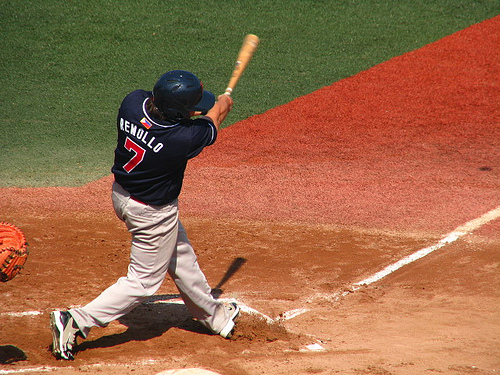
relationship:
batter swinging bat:
[51, 70, 239, 362] [223, 32, 259, 95]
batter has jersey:
[51, 70, 239, 362] [112, 90, 217, 207]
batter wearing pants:
[51, 70, 239, 362] [68, 180, 220, 337]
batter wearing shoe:
[51, 70, 239, 362] [50, 309, 78, 360]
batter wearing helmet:
[51, 70, 239, 362] [149, 69, 216, 117]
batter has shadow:
[51, 70, 239, 362] [73, 258, 245, 352]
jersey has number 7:
[112, 90, 217, 207] [123, 137, 145, 172]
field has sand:
[1, 1, 499, 371] [4, 15, 499, 374]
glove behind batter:
[1, 221, 27, 281] [51, 70, 239, 362]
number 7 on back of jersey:
[123, 137, 145, 172] [112, 90, 217, 207]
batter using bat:
[51, 70, 239, 362] [223, 32, 259, 95]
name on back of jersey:
[119, 119, 164, 154] [112, 90, 217, 207]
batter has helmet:
[51, 70, 239, 362] [149, 69, 216, 117]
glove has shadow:
[1, 221, 27, 281] [0, 345, 29, 364]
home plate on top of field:
[150, 302, 188, 325] [1, 1, 499, 371]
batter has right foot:
[51, 70, 239, 362] [50, 308, 78, 362]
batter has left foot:
[51, 70, 239, 362] [218, 297, 240, 337]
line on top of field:
[275, 206, 498, 325] [1, 1, 499, 371]